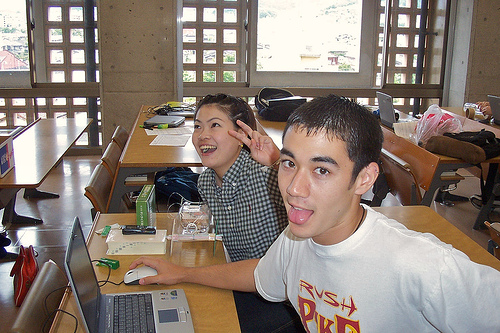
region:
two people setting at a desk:
[121, 88, 498, 326]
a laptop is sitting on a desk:
[57, 214, 205, 331]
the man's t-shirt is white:
[252, 195, 498, 330]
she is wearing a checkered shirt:
[190, 145, 290, 265]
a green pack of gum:
[93, 251, 120, 270]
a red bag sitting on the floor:
[5, 235, 42, 310]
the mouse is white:
[119, 259, 166, 289]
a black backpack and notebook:
[251, 78, 311, 124]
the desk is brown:
[114, 92, 202, 174]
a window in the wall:
[251, 0, 383, 87]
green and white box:
[131, 182, 168, 229]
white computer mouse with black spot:
[123, 263, 168, 288]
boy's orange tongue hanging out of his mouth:
[281, 198, 323, 230]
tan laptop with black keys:
[60, 210, 203, 332]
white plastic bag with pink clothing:
[415, 100, 464, 150]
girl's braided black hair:
[187, 93, 256, 123]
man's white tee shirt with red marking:
[275, 243, 463, 325]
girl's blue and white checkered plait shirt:
[189, 160, 289, 255]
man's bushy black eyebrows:
[273, 138, 343, 164]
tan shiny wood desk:
[90, 207, 235, 331]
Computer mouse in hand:
[120, 263, 162, 286]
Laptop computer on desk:
[62, 215, 208, 330]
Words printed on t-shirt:
[293, 276, 365, 331]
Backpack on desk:
[255, 82, 306, 121]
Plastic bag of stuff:
[415, 103, 460, 147]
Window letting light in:
[246, 0, 371, 82]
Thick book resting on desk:
[105, 227, 168, 255]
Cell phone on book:
[120, 223, 155, 235]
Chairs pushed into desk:
[83, 124, 132, 211]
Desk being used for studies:
[47, 201, 244, 331]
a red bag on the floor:
[9, 237, 49, 309]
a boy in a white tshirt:
[251, 96, 498, 328]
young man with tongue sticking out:
[273, 105, 373, 238]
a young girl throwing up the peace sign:
[191, 95, 283, 170]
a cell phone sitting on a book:
[109, 217, 171, 252]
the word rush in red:
[291, 272, 372, 317]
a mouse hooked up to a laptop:
[37, 218, 198, 330]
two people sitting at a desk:
[103, 95, 420, 332]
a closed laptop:
[142, 112, 194, 130]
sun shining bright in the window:
[253, 17, 380, 79]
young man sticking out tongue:
[266, 80, 382, 241]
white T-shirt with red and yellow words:
[245, 211, 465, 326]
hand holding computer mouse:
[100, 250, 215, 300]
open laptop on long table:
[55, 196, 240, 322]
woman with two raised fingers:
[185, 75, 275, 270]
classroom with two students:
[30, 52, 486, 319]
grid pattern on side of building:
[30, 0, 245, 115]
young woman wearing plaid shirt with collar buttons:
[181, 141, 272, 257]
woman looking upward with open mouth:
[175, 91, 262, 176]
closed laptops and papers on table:
[117, 75, 197, 180]